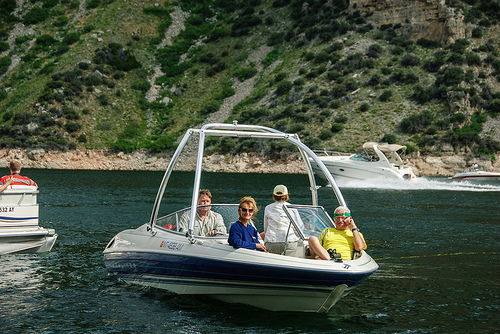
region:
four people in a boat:
[103, 128, 395, 307]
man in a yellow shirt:
[315, 202, 374, 288]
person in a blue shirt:
[229, 192, 266, 260]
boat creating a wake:
[330, 139, 461, 194]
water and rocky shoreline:
[31, 151, 158, 181]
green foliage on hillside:
[9, 5, 175, 137]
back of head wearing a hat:
[265, 179, 292, 205]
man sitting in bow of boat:
[304, 143, 385, 332]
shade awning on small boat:
[375, 137, 419, 179]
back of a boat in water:
[1, 157, 62, 259]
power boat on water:
[93, 115, 412, 321]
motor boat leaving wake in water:
[308, 134, 498, 200]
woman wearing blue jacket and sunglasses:
[228, 193, 264, 251]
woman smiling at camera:
[230, 190, 270, 251]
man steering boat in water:
[177, 185, 229, 239]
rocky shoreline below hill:
[3, 1, 498, 186]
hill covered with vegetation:
[6, 4, 499, 155]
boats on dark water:
[3, 135, 497, 313]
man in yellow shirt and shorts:
[305, 190, 371, 265]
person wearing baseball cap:
[258, 181, 305, 260]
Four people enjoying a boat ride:
[88, 97, 424, 297]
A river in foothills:
[36, 6, 116, 281]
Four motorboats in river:
[5, 100, 490, 295]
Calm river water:
[375, 185, 485, 300]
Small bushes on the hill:
[355, 25, 480, 135]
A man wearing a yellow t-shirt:
[310, 200, 370, 265]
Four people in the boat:
[165, 171, 370, 256]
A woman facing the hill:
[256, 171, 298, 268]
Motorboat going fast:
[306, 115, 498, 210]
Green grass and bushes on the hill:
[30, 20, 165, 142]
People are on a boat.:
[181, 183, 366, 260]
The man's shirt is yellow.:
[324, 229, 354, 251]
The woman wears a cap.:
[272, 185, 289, 197]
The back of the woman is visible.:
[263, 185, 299, 252]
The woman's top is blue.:
[227, 221, 257, 248]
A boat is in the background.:
[307, 142, 422, 190]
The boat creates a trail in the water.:
[420, 178, 498, 189]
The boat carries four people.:
[181, 184, 367, 261]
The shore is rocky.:
[32, 149, 154, 168]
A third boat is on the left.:
[0, 187, 57, 255]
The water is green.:
[0, 165, 499, 332]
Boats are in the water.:
[1, 118, 499, 333]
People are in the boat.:
[101, 183, 376, 319]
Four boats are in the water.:
[0, 120, 497, 331]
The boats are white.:
[0, 117, 495, 328]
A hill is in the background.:
[0, 0, 499, 175]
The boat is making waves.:
[322, 175, 497, 190]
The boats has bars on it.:
[101, 119, 378, 313]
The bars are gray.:
[102, 120, 377, 313]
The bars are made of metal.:
[101, 119, 378, 314]